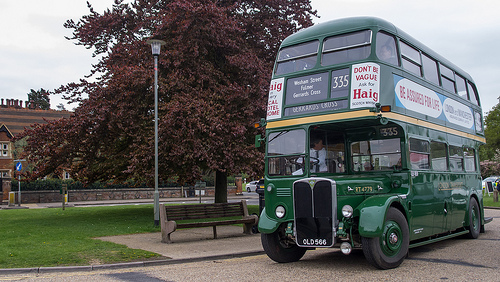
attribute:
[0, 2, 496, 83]
sky — blue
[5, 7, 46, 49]
clouds — white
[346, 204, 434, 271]
tire — rubber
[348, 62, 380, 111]
sign — red and white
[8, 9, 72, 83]
cloud — white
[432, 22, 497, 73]
cloud — white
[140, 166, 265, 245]
bench — wooden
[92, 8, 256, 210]
tree — healthy, colorful, beautiful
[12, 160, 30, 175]
flag — little, blue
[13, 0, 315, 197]
tree — brown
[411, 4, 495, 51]
sky — blue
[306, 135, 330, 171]
driver — right-seated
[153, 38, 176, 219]
light post — grey, tall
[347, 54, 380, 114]
sign — advertisement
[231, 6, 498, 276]
bus — number 335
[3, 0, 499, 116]
sky — blue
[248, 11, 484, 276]
bus — passenger bus, green and white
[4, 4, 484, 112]
clouds — white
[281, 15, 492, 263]
bus — vgreen, v